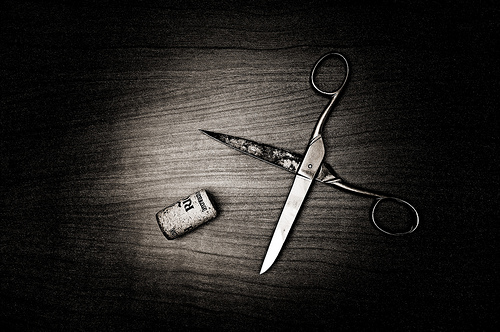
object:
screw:
[307, 162, 314, 168]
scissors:
[183, 40, 429, 280]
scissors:
[196, 43, 453, 283]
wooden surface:
[6, 7, 493, 328]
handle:
[299, 47, 351, 130]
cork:
[152, 187, 219, 248]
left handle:
[352, 185, 435, 241]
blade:
[196, 121, 291, 175]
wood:
[40, 96, 275, 293]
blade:
[256, 174, 311, 276]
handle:
[307, 48, 337, 176]